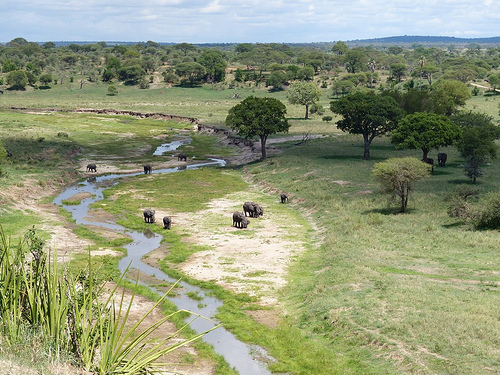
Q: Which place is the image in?
A: It is at the field.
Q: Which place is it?
A: It is a field.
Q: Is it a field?
A: Yes, it is a field.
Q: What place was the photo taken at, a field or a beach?
A: It was taken at a field.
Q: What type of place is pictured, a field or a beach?
A: It is a field.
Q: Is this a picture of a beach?
A: No, the picture is showing a field.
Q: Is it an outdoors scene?
A: Yes, it is outdoors.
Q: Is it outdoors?
A: Yes, it is outdoors.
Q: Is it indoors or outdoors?
A: It is outdoors.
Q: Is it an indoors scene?
A: No, it is outdoors.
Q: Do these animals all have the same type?
A: Yes, all the animals are elephants.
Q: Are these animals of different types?
A: No, all the animals are elephants.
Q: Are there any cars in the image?
A: No, there are no cars.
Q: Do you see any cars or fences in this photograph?
A: No, there are no cars or fences.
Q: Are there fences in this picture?
A: No, there are no fences.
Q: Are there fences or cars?
A: No, there are no fences or cars.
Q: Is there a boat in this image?
A: No, there are no boats.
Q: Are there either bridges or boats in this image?
A: No, there are no boats or bridges.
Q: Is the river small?
A: Yes, the river is small.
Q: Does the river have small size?
A: Yes, the river is small.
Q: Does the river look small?
A: Yes, the river is small.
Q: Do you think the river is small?
A: Yes, the river is small.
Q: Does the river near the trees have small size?
A: Yes, the river is small.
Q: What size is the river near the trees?
A: The river is small.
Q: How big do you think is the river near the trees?
A: The river is small.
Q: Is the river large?
A: No, the river is small.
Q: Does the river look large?
A: No, the river is small.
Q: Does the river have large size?
A: No, the river is small.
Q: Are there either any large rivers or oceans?
A: No, there is a river but it is small.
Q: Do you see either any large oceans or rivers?
A: No, there is a river but it is small.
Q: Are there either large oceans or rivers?
A: No, there is a river but it is small.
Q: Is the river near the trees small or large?
A: The river is small.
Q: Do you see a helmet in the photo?
A: No, there are no helmets.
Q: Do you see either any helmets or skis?
A: No, there are no helmets or skis.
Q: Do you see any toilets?
A: No, there are no toilets.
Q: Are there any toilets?
A: No, there are no toilets.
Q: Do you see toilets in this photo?
A: No, there are no toilets.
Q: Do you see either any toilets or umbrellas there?
A: No, there are no toilets or umbrellas.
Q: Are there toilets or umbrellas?
A: No, there are no toilets or umbrellas.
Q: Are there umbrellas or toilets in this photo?
A: No, there are no toilets or umbrellas.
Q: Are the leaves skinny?
A: Yes, the leaves are skinny.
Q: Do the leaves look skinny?
A: Yes, the leaves are skinny.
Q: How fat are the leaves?
A: The leaves are skinny.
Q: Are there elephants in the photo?
A: Yes, there are elephants.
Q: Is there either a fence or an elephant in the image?
A: Yes, there are elephants.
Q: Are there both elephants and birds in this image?
A: No, there are elephants but no birds.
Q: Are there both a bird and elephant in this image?
A: No, there are elephants but no birds.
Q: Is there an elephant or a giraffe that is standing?
A: Yes, the elephants are standing.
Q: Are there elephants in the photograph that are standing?
A: Yes, there are elephants that are standing.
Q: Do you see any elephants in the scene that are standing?
A: Yes, there are elephants that are standing.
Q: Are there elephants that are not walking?
A: Yes, there are elephants that are standing.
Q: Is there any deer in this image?
A: No, there is no deer.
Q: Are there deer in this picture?
A: No, there are no deer.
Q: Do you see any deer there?
A: No, there is no deer.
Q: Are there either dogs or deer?
A: No, there are no deer or dogs.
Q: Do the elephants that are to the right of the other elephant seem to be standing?
A: Yes, the elephants are standing.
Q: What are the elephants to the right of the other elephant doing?
A: The elephants are standing.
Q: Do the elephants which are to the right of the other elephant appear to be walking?
A: No, the elephants are standing.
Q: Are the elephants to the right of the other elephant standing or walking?
A: The elephants are standing.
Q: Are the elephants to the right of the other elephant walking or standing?
A: The elephants are standing.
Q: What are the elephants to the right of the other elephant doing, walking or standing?
A: The elephants are standing.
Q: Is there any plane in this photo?
A: No, there are no airplanes.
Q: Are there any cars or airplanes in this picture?
A: No, there are no airplanes or cars.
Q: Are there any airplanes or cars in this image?
A: No, there are no airplanes or cars.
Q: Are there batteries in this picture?
A: No, there are no batteries.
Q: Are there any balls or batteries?
A: No, there are no batteries or balls.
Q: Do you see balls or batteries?
A: No, there are no batteries or balls.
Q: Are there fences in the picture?
A: No, there are no fences.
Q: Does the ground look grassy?
A: Yes, the ground is grassy.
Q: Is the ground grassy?
A: Yes, the ground is grassy.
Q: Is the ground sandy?
A: No, the ground is grassy.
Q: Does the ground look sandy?
A: No, the ground is grassy.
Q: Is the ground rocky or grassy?
A: The ground is grassy.